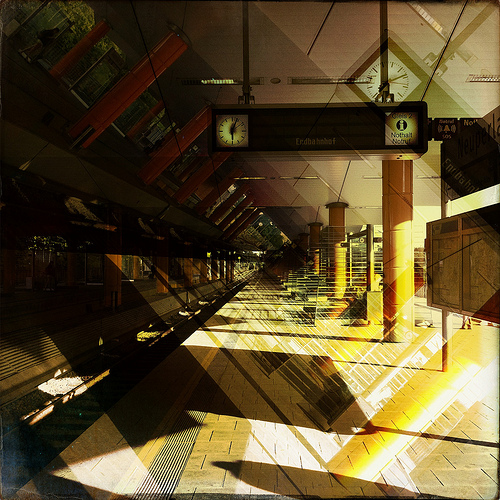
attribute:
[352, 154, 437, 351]
column — cylindrical orange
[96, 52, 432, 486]
station —  train , clock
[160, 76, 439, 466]
station — train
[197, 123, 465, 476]
station — train, sign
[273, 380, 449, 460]
tiles — concrete , train 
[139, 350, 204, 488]
yellow stripe — yellow 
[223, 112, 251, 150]
black hands — black 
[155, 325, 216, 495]
rubber padding — black 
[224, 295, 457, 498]
reflection — very unique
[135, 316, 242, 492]
steel grates — Steel 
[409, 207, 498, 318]
wooden sign — Large , wooden  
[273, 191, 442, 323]
supporting pillars — Large 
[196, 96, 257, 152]
analog clock — not illuminated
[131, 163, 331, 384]
long hallway — Large 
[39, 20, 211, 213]
red pillars — Red 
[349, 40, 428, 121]
white clock — Analog 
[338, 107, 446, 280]
pillar — yellow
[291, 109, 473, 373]
pillar — yellow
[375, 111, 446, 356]
pillar — yellow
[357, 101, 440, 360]
pillar — yellow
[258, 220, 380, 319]
terminal — closed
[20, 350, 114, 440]
tracks — metal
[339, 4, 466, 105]
ceiling — reflective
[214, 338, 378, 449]
shadow — arrow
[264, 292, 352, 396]
shadow — arrow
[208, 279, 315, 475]
shadow — arrow